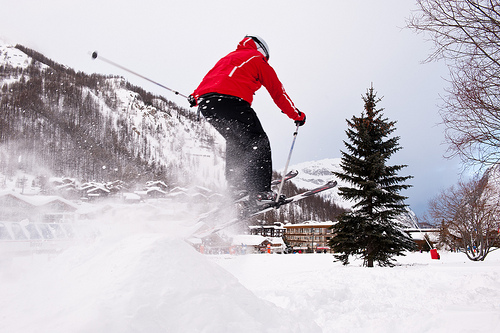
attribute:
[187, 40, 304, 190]
person — wearing, skiing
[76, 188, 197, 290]
snow — here, white, piled, sprayed, top, atop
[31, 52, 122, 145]
mountain — present, here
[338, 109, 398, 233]
tree — covered, tall, lone, evergreen, stoic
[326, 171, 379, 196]
branch — here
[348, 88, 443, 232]
evegreen — here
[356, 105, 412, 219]
evergreen — here, present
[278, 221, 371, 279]
lodge — large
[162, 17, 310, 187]
skier — skiing, jumping, mid jump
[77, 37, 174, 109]
pole — black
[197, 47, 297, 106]
jacket — red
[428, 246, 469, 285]
object — red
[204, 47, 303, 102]
coat — red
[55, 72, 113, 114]
mountains — snowy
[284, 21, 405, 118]
skies — overcast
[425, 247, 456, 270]
box — red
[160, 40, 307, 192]
man — jumping